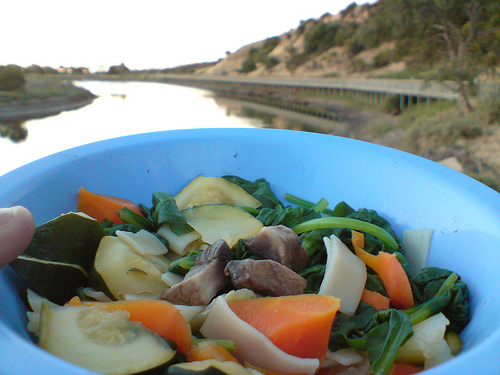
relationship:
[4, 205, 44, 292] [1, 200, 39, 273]
person has finger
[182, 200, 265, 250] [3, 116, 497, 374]
squash in bowl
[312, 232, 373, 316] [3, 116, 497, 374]
egg noodle in bowl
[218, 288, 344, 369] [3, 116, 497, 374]
carrot in bowl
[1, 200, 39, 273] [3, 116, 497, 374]
thumb on bowl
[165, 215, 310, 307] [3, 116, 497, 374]
mushrooms in bowl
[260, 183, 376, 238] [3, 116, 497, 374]
greens in bowl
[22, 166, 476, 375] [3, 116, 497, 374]
food in bowl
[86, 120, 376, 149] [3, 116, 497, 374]
edge of bowl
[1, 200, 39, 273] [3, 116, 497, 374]
finger holding bowl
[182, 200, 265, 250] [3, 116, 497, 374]
cucumber in bowl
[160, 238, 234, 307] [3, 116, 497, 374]
mushrooms in bowl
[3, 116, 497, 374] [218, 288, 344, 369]
bowl has orange food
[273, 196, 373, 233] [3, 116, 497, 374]
spinach in a bowl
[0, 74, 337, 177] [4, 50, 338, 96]
river in background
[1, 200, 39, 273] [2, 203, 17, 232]
person has fingernail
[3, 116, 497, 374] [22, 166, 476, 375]
bowl with food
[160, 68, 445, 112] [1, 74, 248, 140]
highway beside river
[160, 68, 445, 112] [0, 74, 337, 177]
highway beside river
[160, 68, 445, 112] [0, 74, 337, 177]
bridge over river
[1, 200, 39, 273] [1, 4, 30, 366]
thumb on left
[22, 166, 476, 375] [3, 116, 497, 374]
stir fry in blue dish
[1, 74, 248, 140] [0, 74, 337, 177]
curve in river